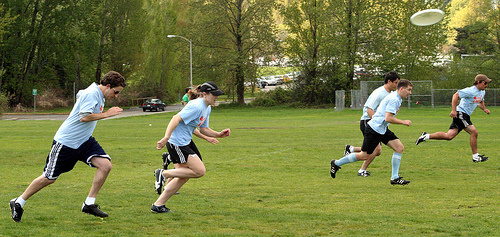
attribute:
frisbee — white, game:
[404, 4, 450, 36]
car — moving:
[131, 92, 173, 117]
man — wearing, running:
[339, 65, 436, 188]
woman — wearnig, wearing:
[144, 41, 234, 204]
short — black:
[172, 132, 207, 159]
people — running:
[34, 45, 490, 207]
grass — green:
[254, 134, 306, 173]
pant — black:
[161, 139, 207, 193]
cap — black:
[192, 84, 240, 102]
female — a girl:
[126, 44, 247, 211]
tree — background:
[34, 13, 355, 103]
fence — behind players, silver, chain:
[412, 77, 451, 116]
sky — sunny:
[273, 2, 314, 45]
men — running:
[337, 59, 479, 147]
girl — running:
[170, 61, 230, 158]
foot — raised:
[137, 151, 204, 207]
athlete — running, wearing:
[367, 45, 456, 146]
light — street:
[164, 11, 215, 80]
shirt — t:
[171, 101, 208, 141]